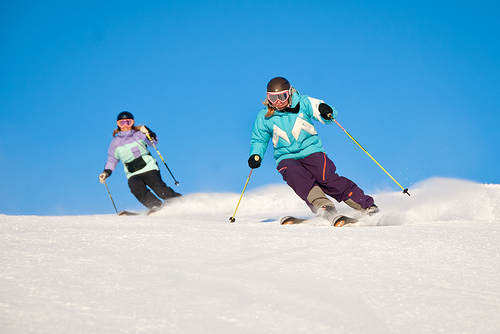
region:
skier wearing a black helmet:
[98, 111, 194, 215]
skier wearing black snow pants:
[124, 170, 182, 214]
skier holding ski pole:
[139, 127, 182, 189]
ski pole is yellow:
[326, 116, 413, 198]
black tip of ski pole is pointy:
[402, 187, 412, 197]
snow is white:
[1, 215, 499, 332]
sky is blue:
[0, 0, 499, 213]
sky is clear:
[0, 2, 499, 214]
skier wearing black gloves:
[247, 153, 262, 166]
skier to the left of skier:
[99, 110, 191, 217]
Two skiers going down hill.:
[68, 36, 447, 243]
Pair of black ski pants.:
[121, 167, 187, 210]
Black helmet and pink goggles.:
[105, 105, 152, 135]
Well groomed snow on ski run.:
[32, 234, 336, 329]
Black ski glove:
[247, 149, 269, 174]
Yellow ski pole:
[218, 158, 267, 233]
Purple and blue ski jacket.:
[92, 130, 183, 177]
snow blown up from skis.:
[416, 171, 487, 242]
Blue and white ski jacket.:
[249, 97, 342, 162]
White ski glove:
[91, 169, 116, 184]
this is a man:
[223, 67, 378, 228]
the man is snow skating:
[241, 72, 382, 219]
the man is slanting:
[235, 71, 375, 236]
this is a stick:
[343, 129, 378, 157]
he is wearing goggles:
[266, 89, 290, 105]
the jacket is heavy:
[273, 110, 310, 147]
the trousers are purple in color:
[296, 159, 328, 180]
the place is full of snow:
[281, 242, 391, 322]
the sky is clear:
[136, 15, 227, 73]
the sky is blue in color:
[161, 32, 213, 69]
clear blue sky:
[172, 74, 215, 110]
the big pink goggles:
[264, 91, 289, 103]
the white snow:
[257, 245, 407, 308]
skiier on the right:
[228, 75, 410, 232]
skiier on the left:
[98, 112, 184, 215]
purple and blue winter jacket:
[102, 131, 162, 171]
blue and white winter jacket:
[246, 100, 341, 162]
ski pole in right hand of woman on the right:
[228, 155, 258, 222]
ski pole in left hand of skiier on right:
[318, 102, 410, 197]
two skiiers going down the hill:
[93, 76, 411, 231]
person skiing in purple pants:
[270, 142, 407, 233]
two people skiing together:
[58, 55, 485, 209]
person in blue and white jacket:
[257, 84, 325, 172]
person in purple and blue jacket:
[94, 94, 165, 186]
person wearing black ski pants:
[118, 161, 202, 206]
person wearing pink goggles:
[101, 108, 151, 135]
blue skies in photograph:
[17, 4, 491, 219]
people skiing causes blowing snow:
[91, 128, 495, 282]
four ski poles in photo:
[48, 100, 439, 242]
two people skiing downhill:
[78, 84, 433, 252]